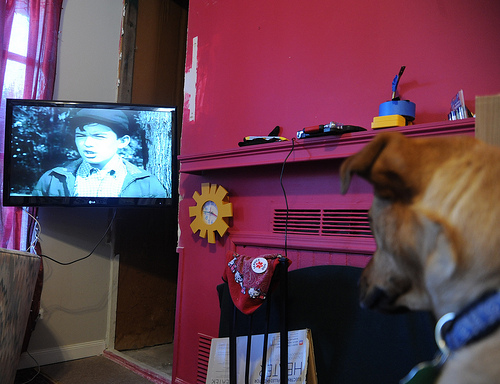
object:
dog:
[338, 129, 500, 384]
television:
[2, 96, 181, 208]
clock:
[188, 182, 234, 244]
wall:
[170, 0, 500, 384]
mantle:
[177, 117, 476, 177]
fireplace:
[169, 162, 379, 384]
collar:
[433, 290, 500, 361]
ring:
[400, 312, 461, 384]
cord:
[280, 137, 297, 332]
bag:
[205, 327, 319, 384]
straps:
[230, 259, 289, 383]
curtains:
[0, 0, 62, 254]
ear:
[336, 130, 402, 196]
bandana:
[221, 252, 294, 314]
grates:
[270, 207, 373, 239]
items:
[447, 89, 473, 121]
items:
[238, 126, 290, 148]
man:
[30, 108, 170, 199]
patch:
[182, 36, 198, 123]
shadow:
[38, 297, 114, 322]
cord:
[19, 207, 118, 266]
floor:
[14, 343, 177, 384]